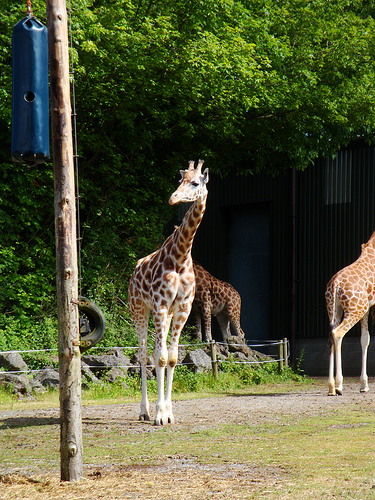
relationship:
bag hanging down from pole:
[13, 15, 60, 159] [45, 5, 83, 480]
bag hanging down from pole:
[11, 15, 48, 155] [54, 75, 91, 295]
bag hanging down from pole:
[7, 1, 51, 166] [44, 3, 86, 484]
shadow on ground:
[0, 415, 155, 431] [1, 375, 373, 497]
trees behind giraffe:
[109, 52, 289, 151] [117, 155, 220, 430]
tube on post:
[80, 296, 107, 353] [50, 1, 83, 481]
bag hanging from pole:
[10, 12, 50, 160] [47, 29, 84, 281]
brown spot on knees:
[157, 357, 164, 368] [154, 347, 178, 367]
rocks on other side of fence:
[178, 340, 289, 390] [71, 335, 327, 372]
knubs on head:
[176, 156, 215, 173] [165, 162, 212, 208]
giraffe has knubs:
[114, 147, 231, 427] [176, 156, 215, 173]